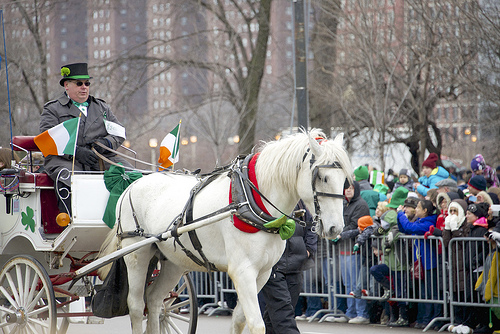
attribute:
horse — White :
[87, 90, 358, 332]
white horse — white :
[95, 122, 355, 332]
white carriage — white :
[0, 169, 199, 332]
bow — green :
[266, 215, 296, 240]